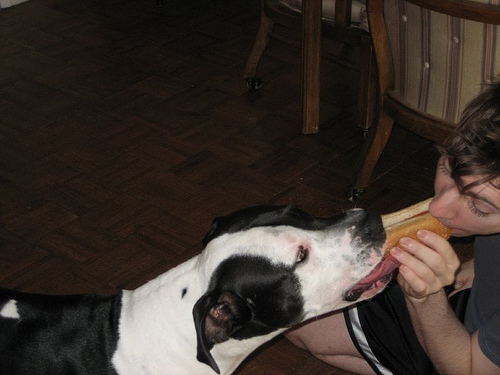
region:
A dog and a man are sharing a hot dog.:
[105, 72, 496, 370]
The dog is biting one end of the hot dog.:
[121, 183, 397, 373]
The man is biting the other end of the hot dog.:
[391, 71, 497, 372]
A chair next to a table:
[232, 1, 353, 143]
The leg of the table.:
[293, 5, 338, 153]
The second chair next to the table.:
[345, 2, 491, 212]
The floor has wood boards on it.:
[25, 52, 161, 254]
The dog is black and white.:
[0, 146, 387, 372]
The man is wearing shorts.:
[270, 287, 450, 372]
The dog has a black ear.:
[180, 280, 251, 371]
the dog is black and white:
[172, 282, 284, 368]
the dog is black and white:
[164, 314, 234, 370]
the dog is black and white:
[95, 265, 243, 368]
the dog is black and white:
[141, 258, 215, 357]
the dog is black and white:
[204, 282, 239, 366]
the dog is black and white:
[108, 205, 288, 348]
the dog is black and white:
[200, 272, 272, 344]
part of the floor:
[65, 116, 207, 182]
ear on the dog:
[196, 298, 259, 355]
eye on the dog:
[297, 242, 312, 272]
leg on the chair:
[365, 115, 383, 186]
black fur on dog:
[50, 321, 95, 352]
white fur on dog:
[147, 316, 186, 363]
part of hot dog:
[380, 211, 459, 234]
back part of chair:
[399, 6, 460, 94]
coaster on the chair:
[235, 71, 274, 91]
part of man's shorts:
[350, 322, 406, 349]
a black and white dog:
[80, 127, 428, 363]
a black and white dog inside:
[61, 141, 386, 373]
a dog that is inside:
[15, 98, 457, 373]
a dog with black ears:
[143, 162, 358, 367]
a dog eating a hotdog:
[150, 145, 487, 327]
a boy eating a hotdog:
[255, 62, 495, 238]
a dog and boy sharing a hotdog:
[198, 37, 493, 307]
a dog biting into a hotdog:
[188, 135, 445, 371]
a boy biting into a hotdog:
[370, 75, 495, 261]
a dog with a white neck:
[47, 110, 449, 370]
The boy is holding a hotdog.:
[278, 83, 498, 373]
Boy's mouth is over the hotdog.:
[338, 80, 498, 325]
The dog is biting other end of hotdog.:
[173, 74, 498, 374]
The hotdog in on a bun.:
[326, 162, 467, 295]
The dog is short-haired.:
[0, 187, 398, 373]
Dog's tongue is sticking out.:
[6, 198, 411, 373]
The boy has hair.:
[346, 51, 498, 316]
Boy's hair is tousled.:
[343, 69, 499, 314]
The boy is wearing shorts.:
[246, 80, 498, 374]